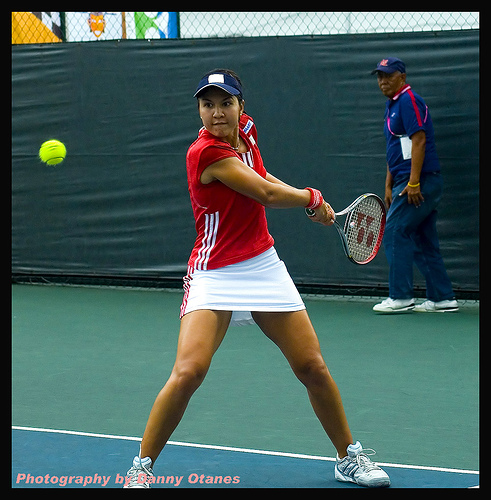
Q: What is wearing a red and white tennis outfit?
A: The woman.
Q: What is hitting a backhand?
A: The woman.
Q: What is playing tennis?
A: The woman.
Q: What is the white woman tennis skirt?
A: The adidas.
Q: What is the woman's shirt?
A: The red Adidas tennis.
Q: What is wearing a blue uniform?
A: The tennis coach.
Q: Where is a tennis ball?
A: In the air.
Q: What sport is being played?
A: Tennis.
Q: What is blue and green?
A: Tennis court.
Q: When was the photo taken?
A: During the daytime.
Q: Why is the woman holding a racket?
A: To hit the ball.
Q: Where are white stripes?
A: On red shirt.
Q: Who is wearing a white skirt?
A: Tennis player.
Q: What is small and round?
A: Tennis ball.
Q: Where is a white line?
A: On the court.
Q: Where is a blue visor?
A: On player's head.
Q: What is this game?
A: Tennis.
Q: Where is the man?
A: Behind the player.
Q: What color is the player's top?
A: Red and white.